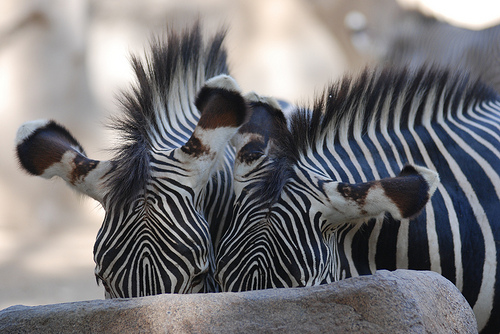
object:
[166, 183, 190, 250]
stripe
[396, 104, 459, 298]
stripe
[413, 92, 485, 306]
stripe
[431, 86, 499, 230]
stripe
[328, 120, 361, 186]
stripe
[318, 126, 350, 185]
stripe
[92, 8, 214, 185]
hair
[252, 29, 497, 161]
hair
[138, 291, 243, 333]
light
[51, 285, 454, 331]
color gray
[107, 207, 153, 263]
stripes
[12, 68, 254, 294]
head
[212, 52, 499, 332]
zebra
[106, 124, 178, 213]
zebra's hair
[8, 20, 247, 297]
zebra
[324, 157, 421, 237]
ear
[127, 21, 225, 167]
fur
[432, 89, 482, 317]
stripe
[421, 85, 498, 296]
stripe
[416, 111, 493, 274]
fur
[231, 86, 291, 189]
ear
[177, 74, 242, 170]
ear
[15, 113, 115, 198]
ear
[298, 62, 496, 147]
zebra's hair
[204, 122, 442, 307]
head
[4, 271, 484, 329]
rock